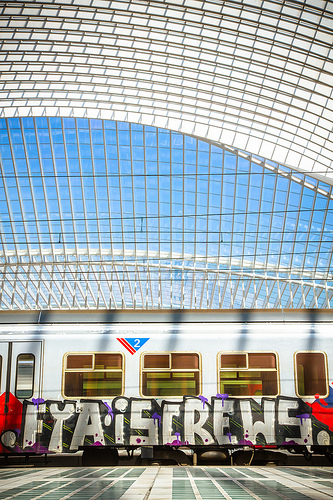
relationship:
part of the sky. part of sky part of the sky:
[219, 180, 328, 303] [235, 185, 331, 309]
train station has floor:
[1, 250, 330, 497] [1, 464, 331, 497]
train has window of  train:
[0, 319, 328, 464] [61, 352, 130, 396]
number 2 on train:
[134, 339, 140, 348] [0, 319, 328, 464]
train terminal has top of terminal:
[5, 5, 329, 499] [1, 3, 330, 307]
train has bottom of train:
[0, 319, 328, 464] [4, 447, 330, 465]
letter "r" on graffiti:
[186, 395, 213, 449] [16, 391, 317, 463]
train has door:
[0, 319, 328, 464] [3, 335, 45, 448]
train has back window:
[0, 319, 328, 464] [292, 348, 332, 399]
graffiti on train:
[16, 391, 317, 463] [0, 319, 328, 464]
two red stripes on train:
[115, 335, 138, 356] [0, 319, 328, 464]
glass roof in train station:
[4, 2, 328, 312] [1, 250, 330, 497]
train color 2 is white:
[0, 319, 328, 464] [132, 337, 142, 349]